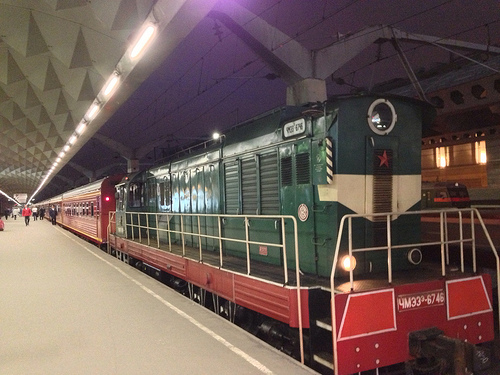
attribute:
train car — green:
[126, 95, 429, 270]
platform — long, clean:
[0, 215, 320, 372]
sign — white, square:
[281, 113, 306, 143]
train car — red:
[61, 173, 125, 244]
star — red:
[373, 144, 396, 173]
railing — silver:
[110, 208, 494, 287]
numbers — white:
[410, 287, 445, 309]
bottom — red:
[108, 229, 493, 370]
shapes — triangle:
[3, 3, 138, 223]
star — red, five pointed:
[377, 150, 399, 169]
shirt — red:
[22, 200, 29, 211]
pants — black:
[22, 216, 29, 223]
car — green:
[113, 100, 425, 268]